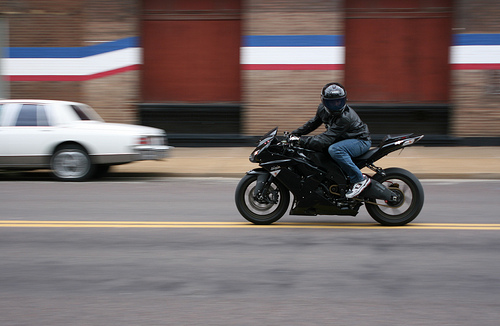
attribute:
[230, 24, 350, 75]
strip — blue, red, white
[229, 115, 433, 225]
motorcycle — black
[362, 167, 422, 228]
wheel — back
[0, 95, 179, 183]
car — white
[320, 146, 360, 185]
jeans — blue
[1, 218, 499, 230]
line — double, solid, yellow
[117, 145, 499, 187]
sidewalk — empty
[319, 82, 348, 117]
helmet — black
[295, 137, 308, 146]
gloves — black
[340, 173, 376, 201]
sneakers — white